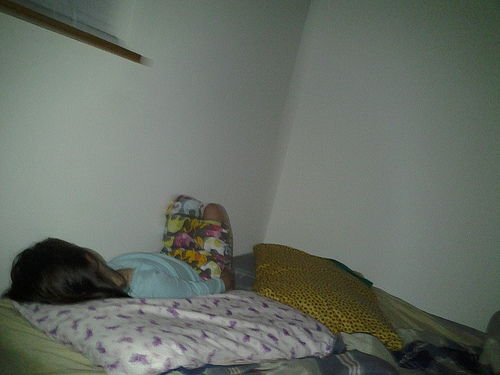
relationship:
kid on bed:
[0, 193, 235, 303] [0, 226, 498, 373]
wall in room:
[256, 3, 496, 335] [2, 0, 499, 374]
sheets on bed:
[1, 313, 48, 367] [2, 253, 494, 371]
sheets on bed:
[381, 287, 477, 340] [2, 253, 494, 371]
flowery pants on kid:
[157, 190, 237, 284] [0, 193, 235, 303]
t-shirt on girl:
[100, 229, 206, 309] [6, 187, 248, 318]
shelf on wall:
[0, 7, 147, 65] [4, 3, 292, 273]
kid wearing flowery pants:
[8, 181, 253, 332] [160, 193, 234, 277]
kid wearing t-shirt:
[8, 181, 253, 332] [104, 242, 230, 303]